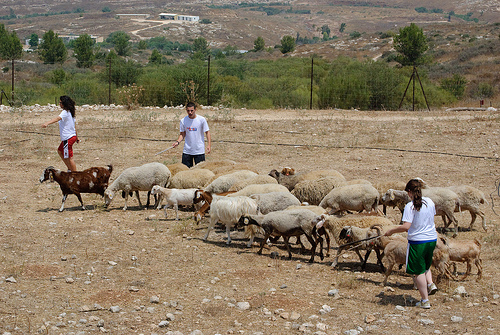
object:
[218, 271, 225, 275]
rock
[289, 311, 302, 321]
rock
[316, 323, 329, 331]
rock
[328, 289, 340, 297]
rock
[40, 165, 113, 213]
goat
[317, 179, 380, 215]
sheep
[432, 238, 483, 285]
sheep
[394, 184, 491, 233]
sheep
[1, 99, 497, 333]
field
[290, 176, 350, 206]
sheep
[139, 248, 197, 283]
small rocks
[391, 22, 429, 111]
tree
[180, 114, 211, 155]
t-shirt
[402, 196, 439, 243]
t-shirt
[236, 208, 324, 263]
goat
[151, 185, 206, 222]
goat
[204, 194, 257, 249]
goat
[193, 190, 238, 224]
goat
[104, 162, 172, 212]
goat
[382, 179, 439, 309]
people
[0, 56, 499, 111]
fence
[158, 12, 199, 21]
house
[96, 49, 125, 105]
tree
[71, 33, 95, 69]
tree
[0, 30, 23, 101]
tree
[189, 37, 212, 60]
tree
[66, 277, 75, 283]
rock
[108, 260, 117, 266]
rock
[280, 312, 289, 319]
rock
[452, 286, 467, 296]
rock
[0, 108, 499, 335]
dirt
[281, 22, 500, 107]
hillside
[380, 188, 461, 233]
goats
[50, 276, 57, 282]
rocks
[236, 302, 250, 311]
rock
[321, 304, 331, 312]
rock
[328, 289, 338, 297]
rock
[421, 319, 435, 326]
rock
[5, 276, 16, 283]
rock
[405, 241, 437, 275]
shorts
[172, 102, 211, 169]
person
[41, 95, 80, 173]
person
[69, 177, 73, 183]
spot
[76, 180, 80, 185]
spot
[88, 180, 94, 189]
spot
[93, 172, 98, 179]
spot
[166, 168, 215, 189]
goat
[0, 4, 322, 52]
hill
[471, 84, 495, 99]
brush